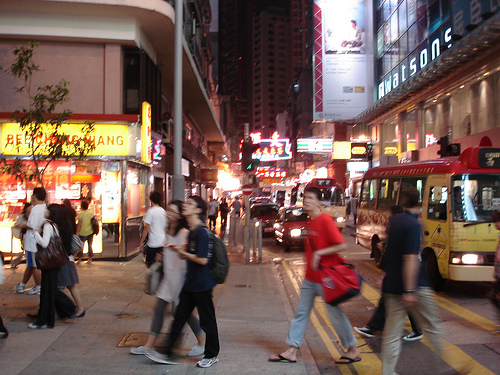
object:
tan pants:
[379, 284, 475, 375]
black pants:
[158, 288, 220, 359]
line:
[439, 294, 498, 340]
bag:
[34, 219, 71, 270]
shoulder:
[42, 220, 53, 230]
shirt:
[303, 213, 349, 283]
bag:
[312, 254, 364, 307]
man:
[141, 192, 231, 369]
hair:
[184, 195, 211, 221]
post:
[245, 198, 251, 264]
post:
[256, 217, 264, 263]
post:
[253, 220, 257, 259]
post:
[230, 214, 236, 247]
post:
[234, 215, 240, 253]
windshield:
[450, 171, 500, 223]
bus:
[354, 145, 499, 293]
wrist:
[404, 285, 416, 299]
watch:
[402, 289, 416, 295]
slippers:
[267, 352, 298, 364]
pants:
[285, 279, 360, 350]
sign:
[243, 182, 253, 197]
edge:
[311, 100, 326, 123]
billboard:
[310, 0, 379, 126]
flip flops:
[334, 351, 362, 365]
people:
[206, 198, 229, 229]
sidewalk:
[225, 256, 286, 340]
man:
[264, 181, 362, 367]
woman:
[129, 198, 206, 356]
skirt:
[54, 260, 79, 288]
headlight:
[450, 250, 491, 267]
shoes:
[22, 285, 40, 295]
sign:
[215, 131, 311, 196]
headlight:
[287, 227, 303, 237]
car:
[274, 204, 309, 251]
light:
[308, 2, 376, 124]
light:
[1, 101, 156, 265]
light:
[213, 165, 243, 196]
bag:
[306, 256, 364, 307]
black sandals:
[264, 351, 299, 365]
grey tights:
[154, 228, 191, 305]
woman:
[26, 203, 86, 318]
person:
[375, 186, 473, 375]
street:
[442, 296, 500, 371]